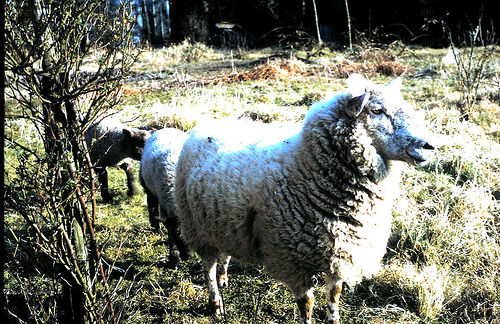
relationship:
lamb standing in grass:
[139, 73, 436, 324] [159, 273, 294, 323]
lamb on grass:
[139, 73, 436, 324] [351, 63, 493, 200]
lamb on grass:
[139, 73, 436, 324] [0, 41, 497, 322]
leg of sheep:
[163, 214, 188, 261] [139, 127, 189, 269]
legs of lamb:
[295, 280, 353, 320] [139, 73, 436, 324]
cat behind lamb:
[89, 117, 154, 210] [142, 124, 188, 269]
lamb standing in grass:
[139, 73, 436, 324] [0, 47, 491, 317]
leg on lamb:
[294, 287, 316, 321] [139, 73, 436, 324]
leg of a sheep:
[203, 254, 222, 305] [140, 70, 438, 315]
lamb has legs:
[180, 90, 450, 322] [206, 250, 228, 320]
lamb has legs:
[180, 90, 450, 322] [296, 285, 346, 322]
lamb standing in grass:
[139, 73, 436, 324] [399, 169, 498, 321]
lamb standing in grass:
[139, 73, 436, 324] [392, 260, 459, 316]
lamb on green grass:
[139, 73, 436, 324] [0, 43, 499, 322]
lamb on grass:
[139, 73, 436, 324] [370, 262, 493, 319]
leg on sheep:
[199, 254, 225, 318] [84, 71, 439, 322]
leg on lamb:
[326, 267, 344, 319] [139, 73, 436, 324]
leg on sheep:
[93, 166, 113, 201] [78, 114, 155, 203]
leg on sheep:
[124, 160, 137, 191] [67, 95, 151, 194]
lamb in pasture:
[139, 73, 436, 324] [3, 25, 499, 322]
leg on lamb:
[326, 275, 351, 322] [139, 73, 436, 324]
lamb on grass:
[139, 73, 436, 324] [53, 22, 491, 264]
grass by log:
[87, 41, 497, 322] [175, 54, 313, 74]